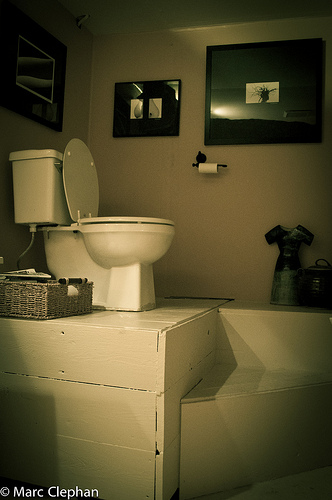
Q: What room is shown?
A: It is a bathroom.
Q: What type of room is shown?
A: It is a bathroom.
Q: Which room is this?
A: It is a bathroom.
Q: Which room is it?
A: It is a bathroom.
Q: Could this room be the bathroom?
A: Yes, it is the bathroom.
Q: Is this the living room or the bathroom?
A: It is the bathroom.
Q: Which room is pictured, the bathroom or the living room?
A: It is the bathroom.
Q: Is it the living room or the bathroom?
A: It is the bathroom.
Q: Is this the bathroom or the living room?
A: It is the bathroom.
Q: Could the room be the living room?
A: No, it is the bathroom.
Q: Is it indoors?
A: Yes, it is indoors.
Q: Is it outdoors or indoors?
A: It is indoors.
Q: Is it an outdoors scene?
A: No, it is indoors.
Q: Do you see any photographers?
A: Yes, there is a photographer.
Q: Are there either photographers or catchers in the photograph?
A: Yes, there is a photographer.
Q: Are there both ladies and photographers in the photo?
A: No, there is a photographer but no ladies.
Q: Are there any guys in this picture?
A: No, there are no guys.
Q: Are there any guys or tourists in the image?
A: No, there are no guys or tourists.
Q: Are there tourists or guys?
A: No, there are no guys or tourists.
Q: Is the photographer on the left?
A: Yes, the photographer is on the left of the image.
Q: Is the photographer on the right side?
A: No, the photographer is on the left of the image.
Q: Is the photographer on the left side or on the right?
A: The photographer is on the left of the image.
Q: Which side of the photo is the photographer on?
A: The photographer is on the left of the image.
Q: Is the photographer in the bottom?
A: Yes, the photographer is in the bottom of the image.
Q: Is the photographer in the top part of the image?
A: No, the photographer is in the bottom of the image.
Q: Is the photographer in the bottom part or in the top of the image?
A: The photographer is in the bottom of the image.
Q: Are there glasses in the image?
A: No, there are no glasses.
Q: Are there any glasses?
A: No, there are no glasses.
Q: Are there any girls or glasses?
A: No, there are no glasses or girls.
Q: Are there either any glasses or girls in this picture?
A: No, there are no glasses or girls.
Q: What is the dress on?
A: The dress is on the wall.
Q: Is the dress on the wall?
A: Yes, the dress is on the wall.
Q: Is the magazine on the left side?
A: Yes, the magazine is on the left of the image.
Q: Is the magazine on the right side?
A: No, the magazine is on the left of the image.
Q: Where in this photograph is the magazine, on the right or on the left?
A: The magazine is on the left of the image.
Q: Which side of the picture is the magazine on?
A: The magazine is on the left of the image.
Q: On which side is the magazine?
A: The magazine is on the left of the image.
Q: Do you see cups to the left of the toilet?
A: No, there is a magazine to the left of the toilet.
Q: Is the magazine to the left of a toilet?
A: Yes, the magazine is to the left of a toilet.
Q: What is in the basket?
A: The magazine is in the basket.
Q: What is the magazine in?
A: The magazine is in the basket.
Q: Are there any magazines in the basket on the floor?
A: Yes, there is a magazine in the basket.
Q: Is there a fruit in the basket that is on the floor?
A: No, there is a magazine in the basket.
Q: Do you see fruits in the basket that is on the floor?
A: No, there is a magazine in the basket.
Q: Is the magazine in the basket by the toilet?
A: Yes, the magazine is in the basket.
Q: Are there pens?
A: No, there are no pens.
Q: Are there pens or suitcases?
A: No, there are no pens or suitcases.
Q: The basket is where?
A: The basket is on the floor.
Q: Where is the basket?
A: The basket is on the floor.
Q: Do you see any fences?
A: No, there are no fences.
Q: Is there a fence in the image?
A: No, there are no fences.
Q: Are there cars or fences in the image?
A: No, there are no fences or cars.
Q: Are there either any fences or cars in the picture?
A: No, there are no fences or cars.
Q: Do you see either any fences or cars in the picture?
A: No, there are no fences or cars.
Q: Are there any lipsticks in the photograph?
A: No, there are no lipsticks.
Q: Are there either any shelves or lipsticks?
A: No, there are no lipsticks or shelves.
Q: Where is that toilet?
A: The toilet is in the bathroom.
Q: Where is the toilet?
A: The toilet is in the bathroom.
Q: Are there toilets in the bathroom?
A: Yes, there is a toilet in the bathroom.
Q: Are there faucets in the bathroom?
A: No, there is a toilet in the bathroom.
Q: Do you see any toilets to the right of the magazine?
A: Yes, there is a toilet to the right of the magazine.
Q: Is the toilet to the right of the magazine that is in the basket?
A: Yes, the toilet is to the right of the magazine.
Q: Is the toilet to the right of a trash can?
A: No, the toilet is to the right of the magazine.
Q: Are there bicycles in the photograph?
A: No, there are no bicycles.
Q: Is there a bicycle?
A: No, there are no bicycles.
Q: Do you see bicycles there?
A: No, there are no bicycles.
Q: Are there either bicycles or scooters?
A: No, there are no bicycles or scooters.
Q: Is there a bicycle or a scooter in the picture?
A: No, there are no bicycles or scooters.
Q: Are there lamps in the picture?
A: No, there are no lamps.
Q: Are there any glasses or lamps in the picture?
A: No, there are no lamps or glasses.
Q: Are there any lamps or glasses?
A: No, there are no lamps or glasses.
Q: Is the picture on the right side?
A: Yes, the picture is on the right of the image.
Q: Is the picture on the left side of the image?
A: No, the picture is on the right of the image.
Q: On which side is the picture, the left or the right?
A: The picture is on the right of the image.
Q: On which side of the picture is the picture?
A: The picture is on the right of the image.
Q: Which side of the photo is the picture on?
A: The picture is on the right of the image.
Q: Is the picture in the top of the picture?
A: Yes, the picture is in the top of the image.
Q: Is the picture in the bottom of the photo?
A: No, the picture is in the top of the image.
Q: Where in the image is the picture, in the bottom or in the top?
A: The picture is in the top of the image.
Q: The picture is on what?
A: The picture is on the wall.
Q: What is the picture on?
A: The picture is on the wall.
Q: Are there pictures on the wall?
A: Yes, there is a picture on the wall.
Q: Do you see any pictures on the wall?
A: Yes, there is a picture on the wall.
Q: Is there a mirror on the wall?
A: No, there is a picture on the wall.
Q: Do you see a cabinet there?
A: No, there are no cabinets.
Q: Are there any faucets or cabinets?
A: No, there are no cabinets or faucets.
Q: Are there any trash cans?
A: No, there are no trash cans.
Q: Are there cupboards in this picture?
A: No, there are no cupboards.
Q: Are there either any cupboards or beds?
A: No, there are no cupboards or beds.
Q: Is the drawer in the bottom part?
A: Yes, the drawer is in the bottom of the image.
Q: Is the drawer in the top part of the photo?
A: No, the drawer is in the bottom of the image.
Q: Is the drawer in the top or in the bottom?
A: The drawer is in the bottom of the image.